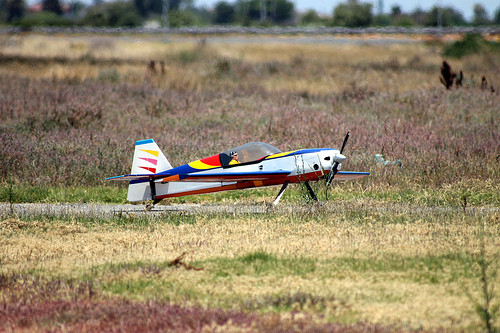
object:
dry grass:
[0, 30, 499, 333]